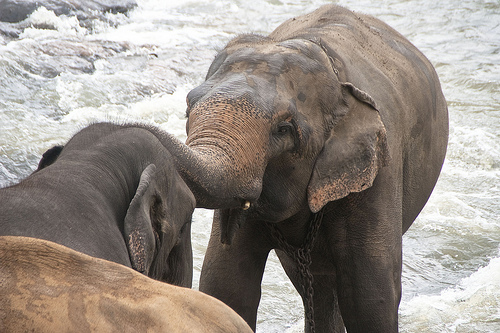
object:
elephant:
[114, 0, 488, 331]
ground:
[43, 14, 181, 101]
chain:
[251, 199, 328, 333]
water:
[448, 22, 495, 224]